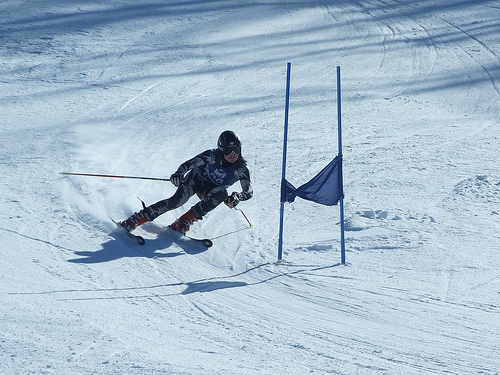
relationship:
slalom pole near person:
[276, 62, 292, 261] [117, 131, 252, 237]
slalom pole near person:
[336, 66, 347, 266] [117, 131, 252, 237]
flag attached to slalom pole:
[281, 157, 340, 204] [276, 62, 292, 261]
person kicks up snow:
[117, 131, 252, 237] [1, 2, 499, 374]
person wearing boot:
[117, 131, 252, 237] [121, 211, 147, 231]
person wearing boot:
[117, 131, 252, 237] [173, 211, 196, 234]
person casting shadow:
[117, 131, 252, 237] [68, 234, 212, 262]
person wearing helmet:
[117, 131, 252, 237] [219, 132, 239, 147]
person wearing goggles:
[117, 131, 252, 237] [221, 145, 241, 154]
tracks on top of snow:
[321, 3, 500, 109] [1, 2, 499, 374]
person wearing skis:
[117, 131, 252, 237] [109, 217, 214, 252]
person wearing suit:
[117, 131, 252, 237] [149, 151, 253, 219]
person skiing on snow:
[117, 131, 252, 237] [1, 2, 499, 374]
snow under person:
[1, 2, 499, 374] [117, 131, 252, 237]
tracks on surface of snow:
[321, 3, 500, 109] [1, 2, 499, 374]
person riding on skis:
[117, 131, 252, 237] [109, 217, 214, 252]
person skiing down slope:
[117, 131, 252, 237] [0, 2, 498, 374]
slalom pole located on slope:
[336, 66, 347, 266] [0, 2, 498, 374]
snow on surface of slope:
[1, 2, 499, 374] [0, 2, 498, 374]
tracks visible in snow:
[321, 3, 500, 109] [1, 2, 499, 374]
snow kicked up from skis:
[1, 2, 499, 374] [109, 217, 214, 252]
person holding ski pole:
[117, 131, 252, 237] [61, 171, 171, 183]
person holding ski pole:
[117, 131, 252, 237] [234, 206, 254, 229]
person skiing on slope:
[117, 131, 252, 237] [0, 2, 498, 374]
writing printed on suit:
[207, 170, 224, 186] [149, 151, 253, 219]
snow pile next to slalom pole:
[342, 210, 436, 233] [336, 66, 347, 266]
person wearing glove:
[117, 131, 252, 237] [169, 174, 185, 187]